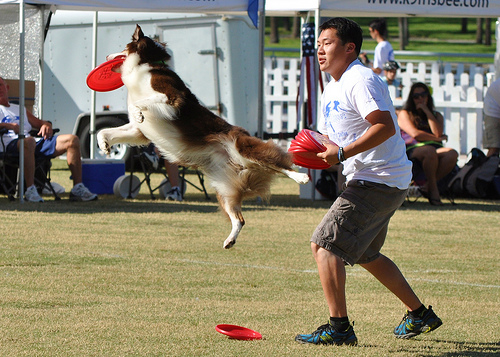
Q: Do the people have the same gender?
A: No, they are both male and female.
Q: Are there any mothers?
A: No, there are no mothers.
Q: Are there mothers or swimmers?
A: No, there are no mothers or swimmers.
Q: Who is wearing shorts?
A: The man is wearing shorts.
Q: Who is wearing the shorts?
A: The man is wearing shorts.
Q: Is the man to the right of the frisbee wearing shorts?
A: Yes, the man is wearing shorts.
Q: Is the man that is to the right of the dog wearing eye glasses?
A: No, the man is wearing shorts.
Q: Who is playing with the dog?
A: The man is playing with the dog.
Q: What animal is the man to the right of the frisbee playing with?
A: The man is playing with the dog.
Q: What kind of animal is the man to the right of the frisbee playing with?
A: The man is playing with the dog.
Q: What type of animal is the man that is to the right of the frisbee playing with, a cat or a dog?
A: The man is playing with a dog.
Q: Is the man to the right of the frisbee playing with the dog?
A: Yes, the man is playing with the dog.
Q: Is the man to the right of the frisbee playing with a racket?
A: No, the man is playing with the dog.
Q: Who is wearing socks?
A: The man is wearing socks.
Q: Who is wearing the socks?
A: The man is wearing socks.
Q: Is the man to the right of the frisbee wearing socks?
A: Yes, the man is wearing socks.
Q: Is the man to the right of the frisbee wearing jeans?
A: No, the man is wearing socks.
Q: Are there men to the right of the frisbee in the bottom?
A: Yes, there is a man to the right of the frisbee.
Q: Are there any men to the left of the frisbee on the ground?
A: No, the man is to the right of the frisbee.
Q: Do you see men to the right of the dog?
A: Yes, there is a man to the right of the dog.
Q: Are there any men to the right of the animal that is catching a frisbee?
A: Yes, there is a man to the right of the dog.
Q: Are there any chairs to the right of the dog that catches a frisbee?
A: No, there is a man to the right of the dog.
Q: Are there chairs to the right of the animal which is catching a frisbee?
A: No, there is a man to the right of the dog.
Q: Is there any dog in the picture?
A: Yes, there is a dog.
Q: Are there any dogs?
A: Yes, there is a dog.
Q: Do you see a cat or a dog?
A: Yes, there is a dog.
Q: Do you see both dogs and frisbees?
A: Yes, there are both a dog and a frisbee.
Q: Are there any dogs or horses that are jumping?
A: Yes, the dog is jumping.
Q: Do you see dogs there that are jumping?
A: Yes, there is a dog that is jumping.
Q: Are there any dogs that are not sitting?
A: Yes, there is a dog that is jumping.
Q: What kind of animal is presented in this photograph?
A: The animal is a dog.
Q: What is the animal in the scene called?
A: The animal is a dog.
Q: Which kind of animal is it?
A: The animal is a dog.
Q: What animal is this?
A: This is a dog.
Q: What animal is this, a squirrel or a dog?
A: This is a dog.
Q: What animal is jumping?
A: The animal is a dog.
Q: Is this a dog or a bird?
A: This is a dog.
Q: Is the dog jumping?
A: Yes, the dog is jumping.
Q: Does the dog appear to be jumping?
A: Yes, the dog is jumping.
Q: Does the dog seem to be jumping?
A: Yes, the dog is jumping.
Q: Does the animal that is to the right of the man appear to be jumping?
A: Yes, the dog is jumping.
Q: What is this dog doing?
A: The dog is jumping.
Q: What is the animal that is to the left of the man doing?
A: The dog is jumping.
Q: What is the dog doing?
A: The dog is jumping.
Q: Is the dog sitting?
A: No, the dog is jumping.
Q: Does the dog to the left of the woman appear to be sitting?
A: No, the dog is jumping.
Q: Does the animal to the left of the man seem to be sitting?
A: No, the dog is jumping.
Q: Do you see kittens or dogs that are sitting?
A: No, there is a dog but it is jumping.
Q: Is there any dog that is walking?
A: No, there is a dog but it is jumping.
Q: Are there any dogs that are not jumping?
A: No, there is a dog but it is jumping.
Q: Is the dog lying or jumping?
A: The dog is jumping.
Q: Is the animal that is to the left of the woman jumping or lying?
A: The dog is jumping.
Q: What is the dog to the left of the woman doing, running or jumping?
A: The dog is jumping.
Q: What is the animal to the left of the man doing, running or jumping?
A: The dog is jumping.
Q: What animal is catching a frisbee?
A: The dog is catching a frisbee.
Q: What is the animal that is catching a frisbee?
A: The animal is a dog.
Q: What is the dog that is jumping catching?
A: The dog is catching a frisbee.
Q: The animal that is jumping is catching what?
A: The dog is catching a frisbee.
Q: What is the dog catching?
A: The dog is catching a frisbee.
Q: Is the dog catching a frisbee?
A: Yes, the dog is catching a frisbee.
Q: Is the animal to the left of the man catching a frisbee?
A: Yes, the dog is catching a frisbee.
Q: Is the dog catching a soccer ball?
A: No, the dog is catching a frisbee.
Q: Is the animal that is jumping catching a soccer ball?
A: No, the dog is catching a frisbee.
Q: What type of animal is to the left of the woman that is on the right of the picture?
A: The animal is a dog.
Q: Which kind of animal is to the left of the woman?
A: The animal is a dog.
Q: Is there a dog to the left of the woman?
A: Yes, there is a dog to the left of the woman.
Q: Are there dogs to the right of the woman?
A: No, the dog is to the left of the woman.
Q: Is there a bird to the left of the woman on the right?
A: No, there is a dog to the left of the woman.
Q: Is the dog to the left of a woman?
A: Yes, the dog is to the left of a woman.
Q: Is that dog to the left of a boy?
A: No, the dog is to the left of a woman.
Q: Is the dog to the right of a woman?
A: No, the dog is to the left of a woman.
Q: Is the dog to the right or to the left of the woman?
A: The dog is to the left of the woman.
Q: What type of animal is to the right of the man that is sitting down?
A: The animal is a dog.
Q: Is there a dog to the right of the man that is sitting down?
A: Yes, there is a dog to the right of the man.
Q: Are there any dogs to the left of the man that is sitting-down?
A: No, the dog is to the right of the man.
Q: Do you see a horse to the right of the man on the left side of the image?
A: No, there is a dog to the right of the man.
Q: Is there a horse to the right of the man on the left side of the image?
A: No, there is a dog to the right of the man.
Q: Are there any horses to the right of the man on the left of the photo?
A: No, there is a dog to the right of the man.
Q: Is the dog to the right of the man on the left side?
A: Yes, the dog is to the right of the man.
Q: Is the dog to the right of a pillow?
A: No, the dog is to the right of the man.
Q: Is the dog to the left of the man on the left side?
A: No, the dog is to the right of the man.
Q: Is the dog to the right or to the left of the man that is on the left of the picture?
A: The dog is to the right of the man.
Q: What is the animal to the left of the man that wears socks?
A: The animal is a dog.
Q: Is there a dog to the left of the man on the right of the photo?
A: Yes, there is a dog to the left of the man.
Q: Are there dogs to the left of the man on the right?
A: Yes, there is a dog to the left of the man.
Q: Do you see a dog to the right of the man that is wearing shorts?
A: No, the dog is to the left of the man.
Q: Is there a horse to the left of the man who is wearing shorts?
A: No, there is a dog to the left of the man.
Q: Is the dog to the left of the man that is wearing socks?
A: Yes, the dog is to the left of the man.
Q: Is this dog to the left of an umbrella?
A: No, the dog is to the left of the man.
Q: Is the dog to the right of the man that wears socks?
A: No, the dog is to the left of the man.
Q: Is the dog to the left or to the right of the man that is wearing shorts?
A: The dog is to the left of the man.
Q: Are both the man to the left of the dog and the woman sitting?
A: Yes, both the man and the woman are sitting.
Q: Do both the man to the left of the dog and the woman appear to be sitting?
A: Yes, both the man and the woman are sitting.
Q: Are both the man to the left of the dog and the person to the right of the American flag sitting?
A: Yes, both the man and the woman are sitting.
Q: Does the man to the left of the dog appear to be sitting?
A: Yes, the man is sitting.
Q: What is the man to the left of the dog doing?
A: The man is sitting.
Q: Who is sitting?
A: The man is sitting.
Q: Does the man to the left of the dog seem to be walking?
A: No, the man is sitting.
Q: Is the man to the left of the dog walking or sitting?
A: The man is sitting.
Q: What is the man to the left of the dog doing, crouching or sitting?
A: The man is sitting.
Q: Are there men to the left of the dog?
A: Yes, there is a man to the left of the dog.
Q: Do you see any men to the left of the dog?
A: Yes, there is a man to the left of the dog.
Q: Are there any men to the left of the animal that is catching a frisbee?
A: Yes, there is a man to the left of the dog.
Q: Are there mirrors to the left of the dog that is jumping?
A: No, there is a man to the left of the dog.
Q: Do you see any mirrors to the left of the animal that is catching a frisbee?
A: No, there is a man to the left of the dog.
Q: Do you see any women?
A: Yes, there is a woman.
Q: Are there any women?
A: Yes, there is a woman.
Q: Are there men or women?
A: Yes, there is a woman.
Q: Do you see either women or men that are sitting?
A: Yes, the woman is sitting.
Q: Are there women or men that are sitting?
A: Yes, the woman is sitting.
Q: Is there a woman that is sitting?
A: Yes, there is a woman that is sitting.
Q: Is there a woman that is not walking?
A: Yes, there is a woman that is sitting.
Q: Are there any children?
A: No, there are no children.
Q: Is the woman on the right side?
A: Yes, the woman is on the right of the image.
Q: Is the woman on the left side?
A: No, the woman is on the right of the image.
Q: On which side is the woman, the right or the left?
A: The woman is on the right of the image.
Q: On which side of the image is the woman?
A: The woman is on the right of the image.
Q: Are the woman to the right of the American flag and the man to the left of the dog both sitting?
A: Yes, both the woman and the man are sitting.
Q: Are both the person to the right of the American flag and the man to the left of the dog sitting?
A: Yes, both the woman and the man are sitting.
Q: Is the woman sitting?
A: Yes, the woman is sitting.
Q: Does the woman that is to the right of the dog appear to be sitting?
A: Yes, the woman is sitting.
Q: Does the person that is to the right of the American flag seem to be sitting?
A: Yes, the woman is sitting.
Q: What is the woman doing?
A: The woman is sitting.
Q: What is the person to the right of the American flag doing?
A: The woman is sitting.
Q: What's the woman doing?
A: The woman is sitting.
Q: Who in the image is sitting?
A: The woman is sitting.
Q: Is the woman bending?
A: No, the woman is sitting.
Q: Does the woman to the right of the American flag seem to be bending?
A: No, the woman is sitting.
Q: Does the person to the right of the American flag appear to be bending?
A: No, the woman is sitting.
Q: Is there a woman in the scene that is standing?
A: No, there is a woman but she is sitting.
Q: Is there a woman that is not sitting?
A: No, there is a woman but she is sitting.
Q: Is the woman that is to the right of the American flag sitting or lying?
A: The woman is sitting.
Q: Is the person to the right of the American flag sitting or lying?
A: The woman is sitting.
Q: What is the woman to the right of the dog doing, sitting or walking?
A: The woman is sitting.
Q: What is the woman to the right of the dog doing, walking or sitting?
A: The woman is sitting.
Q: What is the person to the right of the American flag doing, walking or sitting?
A: The woman is sitting.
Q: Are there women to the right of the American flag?
A: Yes, there is a woman to the right of the American flag.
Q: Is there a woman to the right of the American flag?
A: Yes, there is a woman to the right of the American flag.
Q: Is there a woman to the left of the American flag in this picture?
A: No, the woman is to the right of the American flag.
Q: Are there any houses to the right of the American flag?
A: No, there is a woman to the right of the American flag.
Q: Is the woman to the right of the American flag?
A: Yes, the woman is to the right of the American flag.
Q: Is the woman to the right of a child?
A: No, the woman is to the right of the American flag.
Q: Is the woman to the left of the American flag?
A: No, the woman is to the right of the American flag.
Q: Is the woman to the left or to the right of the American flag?
A: The woman is to the right of the American flag.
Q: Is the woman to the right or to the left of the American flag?
A: The woman is to the right of the American flag.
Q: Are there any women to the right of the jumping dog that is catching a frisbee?
A: Yes, there is a woman to the right of the dog.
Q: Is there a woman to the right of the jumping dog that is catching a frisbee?
A: Yes, there is a woman to the right of the dog.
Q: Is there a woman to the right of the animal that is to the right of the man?
A: Yes, there is a woman to the right of the dog.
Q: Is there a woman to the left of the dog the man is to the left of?
A: No, the woman is to the right of the dog.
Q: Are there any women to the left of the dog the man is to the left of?
A: No, the woman is to the right of the dog.